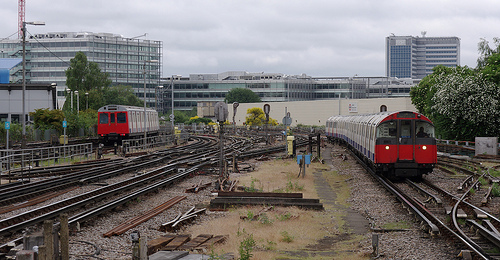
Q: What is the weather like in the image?
A: It is cloudy.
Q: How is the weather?
A: It is cloudy.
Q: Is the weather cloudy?
A: Yes, it is cloudy.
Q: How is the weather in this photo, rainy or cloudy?
A: It is cloudy.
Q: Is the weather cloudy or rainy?
A: It is cloudy.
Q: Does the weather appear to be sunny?
A: No, it is cloudy.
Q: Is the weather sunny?
A: No, it is cloudy.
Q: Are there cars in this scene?
A: No, there are no cars.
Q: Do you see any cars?
A: No, there are no cars.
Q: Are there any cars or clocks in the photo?
A: No, there are no cars or clocks.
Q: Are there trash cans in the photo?
A: No, there are no trash cans.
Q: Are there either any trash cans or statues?
A: No, there are no trash cans or statues.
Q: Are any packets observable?
A: No, there are no packets.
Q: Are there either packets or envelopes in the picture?
A: No, there are no packets or envelopes.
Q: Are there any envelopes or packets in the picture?
A: No, there are no packets or envelopes.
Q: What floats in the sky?
A: The clouds float in the sky.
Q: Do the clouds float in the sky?
A: Yes, the clouds float in the sky.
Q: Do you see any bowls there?
A: No, there are no bowls.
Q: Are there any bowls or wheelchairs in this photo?
A: No, there are no bowls or wheelchairs.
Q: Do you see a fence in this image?
A: Yes, there is a fence.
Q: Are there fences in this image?
A: Yes, there is a fence.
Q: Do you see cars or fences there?
A: Yes, there is a fence.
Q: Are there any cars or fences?
A: Yes, there is a fence.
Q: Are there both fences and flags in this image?
A: No, there is a fence but no flags.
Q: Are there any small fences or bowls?
A: Yes, there is a small fence.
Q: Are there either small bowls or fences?
A: Yes, there is a small fence.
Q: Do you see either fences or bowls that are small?
A: Yes, the fence is small.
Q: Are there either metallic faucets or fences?
A: Yes, there is a metal fence.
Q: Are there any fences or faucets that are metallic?
A: Yes, the fence is metallic.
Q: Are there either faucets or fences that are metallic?
A: Yes, the fence is metallic.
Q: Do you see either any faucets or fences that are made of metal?
A: Yes, the fence is made of metal.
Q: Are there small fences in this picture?
A: Yes, there is a small fence.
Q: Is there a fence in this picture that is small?
A: Yes, there is a fence that is small.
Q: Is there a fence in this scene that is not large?
A: Yes, there is a small fence.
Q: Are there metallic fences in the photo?
A: Yes, there is a metal fence.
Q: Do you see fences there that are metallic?
A: Yes, there is a fence that is metallic.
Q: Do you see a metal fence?
A: Yes, there is a fence that is made of metal.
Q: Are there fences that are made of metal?
A: Yes, there is a fence that is made of metal.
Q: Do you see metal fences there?
A: Yes, there is a fence that is made of metal.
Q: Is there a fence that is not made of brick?
A: Yes, there is a fence that is made of metal.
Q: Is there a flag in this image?
A: No, there are no flags.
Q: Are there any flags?
A: No, there are no flags.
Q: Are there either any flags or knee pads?
A: No, there are no flags or knee pads.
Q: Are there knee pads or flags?
A: No, there are no flags or knee pads.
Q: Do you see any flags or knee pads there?
A: No, there are no flags or knee pads.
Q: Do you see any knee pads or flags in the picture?
A: No, there are no flags or knee pads.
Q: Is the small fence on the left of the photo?
A: Yes, the fence is on the left of the image.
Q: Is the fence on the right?
A: No, the fence is on the left of the image.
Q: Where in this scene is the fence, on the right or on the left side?
A: The fence is on the left of the image.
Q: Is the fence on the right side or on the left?
A: The fence is on the left of the image.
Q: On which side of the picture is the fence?
A: The fence is on the left of the image.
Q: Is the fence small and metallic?
A: Yes, the fence is small and metallic.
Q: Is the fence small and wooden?
A: No, the fence is small but metallic.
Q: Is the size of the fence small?
A: Yes, the fence is small.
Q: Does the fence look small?
A: Yes, the fence is small.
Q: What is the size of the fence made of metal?
A: The fence is small.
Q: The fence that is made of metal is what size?
A: The fence is small.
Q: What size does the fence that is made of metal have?
A: The fence has small size.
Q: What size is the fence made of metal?
A: The fence is small.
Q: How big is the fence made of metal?
A: The fence is small.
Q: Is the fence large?
A: No, the fence is small.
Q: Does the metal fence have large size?
A: No, the fence is small.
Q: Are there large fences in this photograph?
A: No, there is a fence but it is small.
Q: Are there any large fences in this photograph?
A: No, there is a fence but it is small.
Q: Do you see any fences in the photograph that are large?
A: No, there is a fence but it is small.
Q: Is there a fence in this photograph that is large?
A: No, there is a fence but it is small.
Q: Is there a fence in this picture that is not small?
A: No, there is a fence but it is small.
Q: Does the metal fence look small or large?
A: The fence is small.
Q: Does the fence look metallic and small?
A: Yes, the fence is metallic and small.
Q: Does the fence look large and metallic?
A: No, the fence is metallic but small.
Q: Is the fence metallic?
A: Yes, the fence is metallic.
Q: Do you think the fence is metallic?
A: Yes, the fence is metallic.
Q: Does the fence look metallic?
A: Yes, the fence is metallic.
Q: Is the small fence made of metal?
A: Yes, the fence is made of metal.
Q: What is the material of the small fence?
A: The fence is made of metal.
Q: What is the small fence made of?
A: The fence is made of metal.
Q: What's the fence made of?
A: The fence is made of metal.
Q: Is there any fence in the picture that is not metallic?
A: No, there is a fence but it is metallic.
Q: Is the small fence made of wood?
A: No, the fence is made of metal.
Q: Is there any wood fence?
A: No, there is a fence but it is made of metal.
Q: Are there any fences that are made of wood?
A: No, there is a fence but it is made of metal.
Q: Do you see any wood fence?
A: No, there is a fence but it is made of metal.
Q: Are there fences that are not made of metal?
A: No, there is a fence but it is made of metal.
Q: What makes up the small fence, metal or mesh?
A: The fence is made of metal.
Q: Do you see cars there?
A: No, there are no cars.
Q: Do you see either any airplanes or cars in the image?
A: No, there are no cars or airplanes.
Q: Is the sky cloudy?
A: Yes, the sky is cloudy.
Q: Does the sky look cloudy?
A: Yes, the sky is cloudy.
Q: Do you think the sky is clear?
A: No, the sky is cloudy.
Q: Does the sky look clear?
A: No, the sky is cloudy.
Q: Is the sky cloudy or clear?
A: The sky is cloudy.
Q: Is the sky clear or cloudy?
A: The sky is cloudy.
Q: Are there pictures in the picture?
A: No, there are no pictures.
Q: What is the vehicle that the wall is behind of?
A: The vehicle is a train.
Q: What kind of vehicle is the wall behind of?
A: The wall is behind the train.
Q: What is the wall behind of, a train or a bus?
A: The wall is behind a train.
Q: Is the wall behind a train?
A: Yes, the wall is behind a train.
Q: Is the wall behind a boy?
A: No, the wall is behind a train.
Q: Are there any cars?
A: No, there are no cars.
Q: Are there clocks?
A: No, there are no clocks.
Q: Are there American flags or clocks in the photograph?
A: No, there are no clocks or American flags.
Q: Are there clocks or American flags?
A: No, there are no clocks or American flags.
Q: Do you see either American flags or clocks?
A: No, there are no clocks or American flags.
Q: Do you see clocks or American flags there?
A: No, there are no clocks or American flags.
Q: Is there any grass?
A: Yes, there is grass.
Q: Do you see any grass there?
A: Yes, there is grass.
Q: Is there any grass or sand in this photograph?
A: Yes, there is grass.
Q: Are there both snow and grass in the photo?
A: No, there is grass but no snow.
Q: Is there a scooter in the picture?
A: No, there are no scooters.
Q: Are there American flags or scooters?
A: No, there are no scooters or American flags.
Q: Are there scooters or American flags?
A: No, there are no scooters or American flags.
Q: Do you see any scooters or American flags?
A: No, there are no scooters or American flags.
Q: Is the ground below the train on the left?
A: Yes, the ground is below the train.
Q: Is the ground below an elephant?
A: No, the ground is below the train.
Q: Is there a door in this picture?
A: Yes, there is a door.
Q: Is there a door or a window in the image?
A: Yes, there is a door.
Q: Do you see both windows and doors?
A: Yes, there are both a door and a window.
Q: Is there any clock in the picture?
A: No, there are no clocks.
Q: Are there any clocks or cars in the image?
A: No, there are no clocks or cars.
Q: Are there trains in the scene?
A: Yes, there is a train.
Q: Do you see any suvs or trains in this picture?
A: Yes, there is a train.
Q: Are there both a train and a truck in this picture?
A: No, there is a train but no trucks.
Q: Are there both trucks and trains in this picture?
A: No, there is a train but no trucks.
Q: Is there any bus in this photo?
A: No, there are no buses.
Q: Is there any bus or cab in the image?
A: No, there are no buses or taxis.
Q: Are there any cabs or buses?
A: No, there are no buses or cabs.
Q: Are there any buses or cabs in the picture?
A: No, there are no buses or cabs.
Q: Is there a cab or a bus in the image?
A: No, there are no buses or taxis.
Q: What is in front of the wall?
A: The train is in front of the wall.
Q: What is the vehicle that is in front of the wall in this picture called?
A: The vehicle is a train.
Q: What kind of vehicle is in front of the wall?
A: The vehicle is a train.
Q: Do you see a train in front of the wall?
A: Yes, there is a train in front of the wall.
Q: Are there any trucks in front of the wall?
A: No, there is a train in front of the wall.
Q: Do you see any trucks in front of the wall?
A: No, there is a train in front of the wall.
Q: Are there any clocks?
A: No, there are no clocks.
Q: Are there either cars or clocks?
A: No, there are no clocks or cars.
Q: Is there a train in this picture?
A: Yes, there is a train.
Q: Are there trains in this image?
A: Yes, there is a train.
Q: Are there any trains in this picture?
A: Yes, there is a train.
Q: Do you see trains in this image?
A: Yes, there is a train.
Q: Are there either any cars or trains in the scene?
A: Yes, there is a train.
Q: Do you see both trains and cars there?
A: No, there is a train but no cars.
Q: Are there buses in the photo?
A: No, there are no buses.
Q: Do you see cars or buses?
A: No, there are no buses or cars.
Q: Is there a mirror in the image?
A: No, there are no mirrors.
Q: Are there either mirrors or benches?
A: No, there are no mirrors or benches.